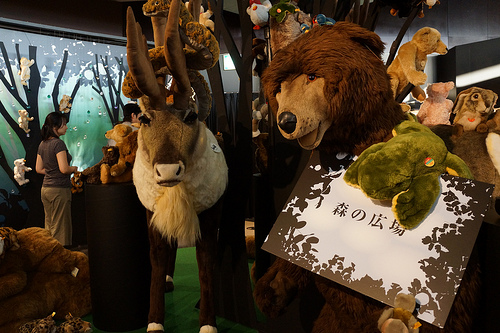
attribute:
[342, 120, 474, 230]
toy frog — green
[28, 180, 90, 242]
pants — tan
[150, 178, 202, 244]
beard — tan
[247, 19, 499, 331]
teddy bear — large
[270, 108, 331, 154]
ground — brown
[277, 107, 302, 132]
nose — black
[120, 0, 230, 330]
moose — large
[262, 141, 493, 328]
b&w sign — white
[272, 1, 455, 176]
bear — stuffed, toy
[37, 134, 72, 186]
shirt — brown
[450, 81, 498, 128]
stuffed rabbit — small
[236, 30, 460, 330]
bear — large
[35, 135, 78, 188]
shirt — Brown 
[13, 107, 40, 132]
teddy bear — small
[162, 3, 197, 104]
antler — deer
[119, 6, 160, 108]
antler — deer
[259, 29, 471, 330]
bear — stuffed, teddy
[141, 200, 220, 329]
legs — goat's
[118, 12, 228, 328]
goat — toy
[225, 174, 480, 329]
board — brown, white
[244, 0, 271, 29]
bird — stuffed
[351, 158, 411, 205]
nose — green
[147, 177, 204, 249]
hair — blonde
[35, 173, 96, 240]
skirt — beige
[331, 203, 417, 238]
lettering — Asian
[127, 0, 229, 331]
goat — toy, stuffed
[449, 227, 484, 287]
border — decorative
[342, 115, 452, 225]
stuffed anmal — green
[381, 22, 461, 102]
stuffed bear — light brown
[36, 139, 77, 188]
brown shirt — brown 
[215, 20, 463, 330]
teddy bear — large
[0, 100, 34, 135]
branch — tree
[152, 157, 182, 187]
nose — brown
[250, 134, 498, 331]
sign — black